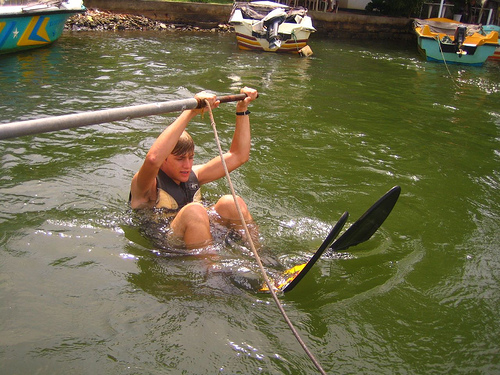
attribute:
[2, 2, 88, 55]
boat — blue, yellow, parked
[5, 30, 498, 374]
water — green, white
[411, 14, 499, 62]
boat — blue, parked, aqua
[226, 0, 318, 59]
boat — white, yellow, parked, brown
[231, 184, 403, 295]
skis — black, yellow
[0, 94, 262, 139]
ski pole — grey, metal, gray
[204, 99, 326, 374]
rope — brown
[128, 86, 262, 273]
man — young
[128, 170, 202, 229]
life vest — black, tan, yellow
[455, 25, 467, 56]
motor — black, out of the water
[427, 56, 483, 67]
stripe — blue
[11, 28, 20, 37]
star — white, small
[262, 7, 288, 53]
motor — black, white